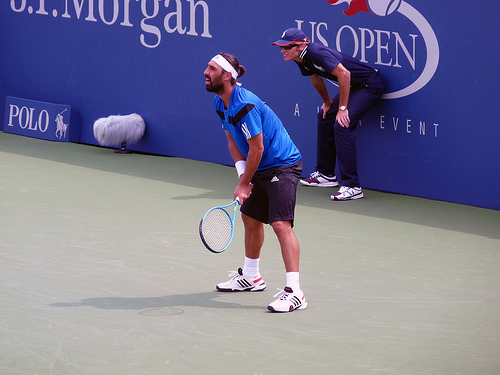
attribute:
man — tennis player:
[175, 43, 310, 332]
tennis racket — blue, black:
[188, 196, 250, 249]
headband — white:
[209, 44, 262, 88]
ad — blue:
[2, 93, 80, 145]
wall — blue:
[445, 30, 491, 50]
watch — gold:
[334, 97, 366, 118]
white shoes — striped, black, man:
[227, 265, 311, 319]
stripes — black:
[286, 300, 311, 306]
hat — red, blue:
[272, 29, 313, 50]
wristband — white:
[229, 160, 254, 182]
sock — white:
[241, 254, 263, 276]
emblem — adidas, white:
[267, 169, 283, 189]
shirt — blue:
[203, 98, 305, 176]